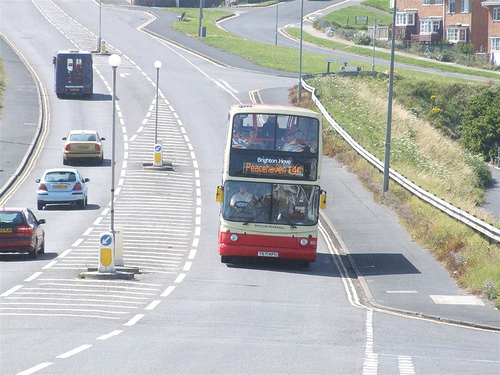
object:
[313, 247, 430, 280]
shadow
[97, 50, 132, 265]
pole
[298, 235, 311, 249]
headlight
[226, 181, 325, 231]
window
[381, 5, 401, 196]
pole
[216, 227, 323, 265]
bumper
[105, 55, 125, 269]
pole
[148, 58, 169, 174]
pole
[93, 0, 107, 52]
pole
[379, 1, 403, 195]
pole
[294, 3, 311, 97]
pole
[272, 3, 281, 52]
pole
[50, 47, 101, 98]
truck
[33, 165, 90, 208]
car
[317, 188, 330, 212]
mirror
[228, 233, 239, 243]
light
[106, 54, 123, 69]
light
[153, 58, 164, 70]
light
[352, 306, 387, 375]
line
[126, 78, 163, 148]
line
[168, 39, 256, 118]
line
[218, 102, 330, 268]
bus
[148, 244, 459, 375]
road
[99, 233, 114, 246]
arrow